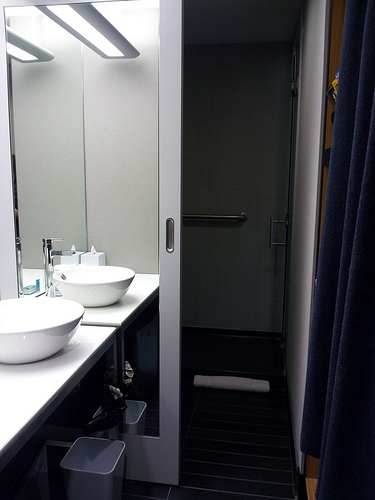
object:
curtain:
[299, 0, 375, 500]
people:
[10, 154, 21, 250]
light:
[33, 2, 140, 59]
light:
[5, 24, 55, 64]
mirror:
[2, 4, 89, 298]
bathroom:
[0, 0, 375, 500]